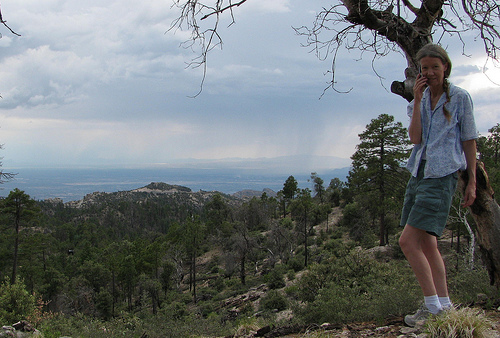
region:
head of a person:
[406, 46, 453, 91]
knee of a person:
[396, 226, 416, 256]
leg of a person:
[403, 242, 439, 289]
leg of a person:
[428, 240, 455, 294]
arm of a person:
[449, 95, 489, 189]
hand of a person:
[457, 189, 489, 210]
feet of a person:
[400, 300, 457, 335]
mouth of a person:
[423, 69, 438, 88]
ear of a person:
[438, 57, 451, 73]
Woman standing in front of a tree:
[396, 42, 485, 327]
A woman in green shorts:
[393, 42, 478, 329]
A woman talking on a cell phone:
[411, 43, 458, 109]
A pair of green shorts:
[398, 151, 456, 240]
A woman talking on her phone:
[394, 43, 479, 330]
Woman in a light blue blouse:
[406, 42, 477, 177]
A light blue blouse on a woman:
[402, 81, 481, 178]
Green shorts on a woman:
[397, 154, 456, 238]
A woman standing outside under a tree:
[396, 40, 478, 323]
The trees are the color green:
[19, 223, 178, 290]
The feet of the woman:
[403, 299, 460, 332]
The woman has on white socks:
[418, 288, 454, 313]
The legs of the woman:
[396, 227, 453, 302]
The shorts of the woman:
[396, 156, 462, 238]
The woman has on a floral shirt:
[398, 80, 483, 183]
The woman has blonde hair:
[406, 41, 461, 124]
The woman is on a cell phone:
[399, 35, 486, 158]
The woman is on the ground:
[359, 32, 497, 335]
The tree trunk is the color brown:
[335, 2, 455, 49]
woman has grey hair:
[415, 36, 451, 87]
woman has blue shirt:
[406, 86, 473, 180]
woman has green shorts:
[407, 180, 474, 257]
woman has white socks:
[422, 276, 458, 306]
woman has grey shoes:
[406, 304, 438, 336]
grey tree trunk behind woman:
[342, 2, 497, 205]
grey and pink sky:
[30, 27, 268, 177]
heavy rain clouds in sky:
[38, 13, 204, 140]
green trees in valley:
[0, 162, 342, 307]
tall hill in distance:
[120, 173, 271, 216]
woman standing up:
[379, 40, 487, 336]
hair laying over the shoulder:
[438, 75, 455, 126]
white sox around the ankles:
[418, 292, 454, 312]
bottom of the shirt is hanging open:
[413, 148, 438, 183]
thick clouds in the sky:
[0, 1, 499, 116]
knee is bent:
[392, 222, 416, 254]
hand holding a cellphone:
[415, 63, 425, 86]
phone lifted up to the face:
[414, 64, 428, 88]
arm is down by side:
[453, 108, 482, 219]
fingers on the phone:
[416, 70, 430, 88]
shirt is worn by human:
[404, 77, 475, 179]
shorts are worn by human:
[397, 167, 457, 237]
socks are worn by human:
[422, 293, 454, 313]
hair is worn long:
[416, 42, 457, 117]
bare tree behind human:
[167, 2, 499, 284]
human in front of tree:
[392, 43, 482, 323]